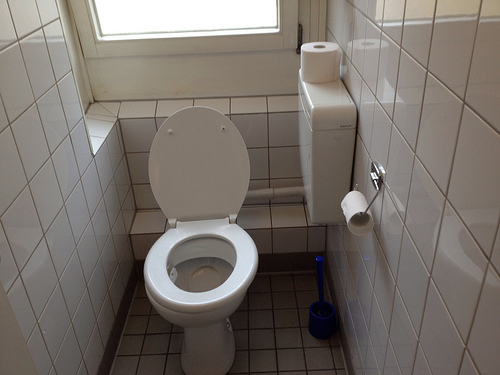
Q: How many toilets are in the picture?
A: One.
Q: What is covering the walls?
A: Tile.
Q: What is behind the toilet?
A: Window.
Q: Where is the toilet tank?
A: Right wall.